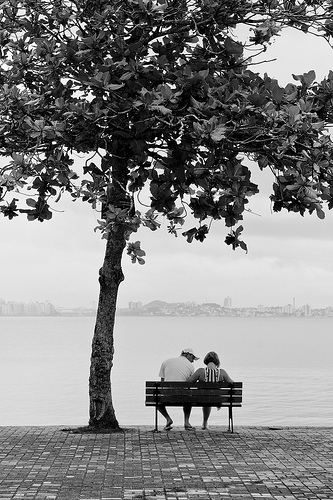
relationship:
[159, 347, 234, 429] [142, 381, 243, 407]
couple sitting on bench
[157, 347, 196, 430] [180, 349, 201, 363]
man wearing hat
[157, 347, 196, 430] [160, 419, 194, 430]
man wearing flip flops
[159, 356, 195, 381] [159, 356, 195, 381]
shirt has shirt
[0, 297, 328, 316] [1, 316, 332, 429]
buildings are beyond water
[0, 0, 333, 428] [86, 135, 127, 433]
tree has a trunk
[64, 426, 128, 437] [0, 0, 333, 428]
dirt below tree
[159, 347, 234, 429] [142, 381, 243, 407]
couple sitting on a bench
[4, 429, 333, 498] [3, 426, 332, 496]
walkway made of cobblestone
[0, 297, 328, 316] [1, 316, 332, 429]
city beyond water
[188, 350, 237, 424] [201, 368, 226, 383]
woman wearing a shirt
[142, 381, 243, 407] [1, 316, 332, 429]
bench by water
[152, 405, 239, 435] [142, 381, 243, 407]
legs on bench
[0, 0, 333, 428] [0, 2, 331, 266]
tree has leaves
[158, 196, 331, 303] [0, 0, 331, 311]
clouds in sky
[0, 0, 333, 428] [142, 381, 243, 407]
tree near bench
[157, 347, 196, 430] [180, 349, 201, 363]
man wearing a hat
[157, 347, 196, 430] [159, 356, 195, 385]
man wearing a shirt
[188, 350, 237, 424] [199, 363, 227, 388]
person wearing a tank top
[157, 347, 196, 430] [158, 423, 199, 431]
man wearing sandals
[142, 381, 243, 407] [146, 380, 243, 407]
bench made of wood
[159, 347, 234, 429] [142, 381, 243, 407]
couple on bench